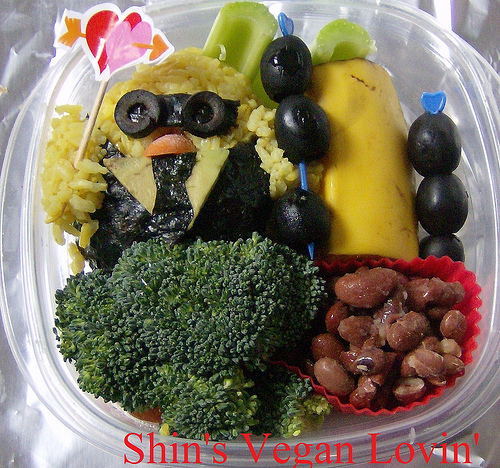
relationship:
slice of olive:
[110, 90, 164, 140] [107, 93, 161, 145]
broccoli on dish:
[43, 223, 355, 434] [1, 2, 483, 456]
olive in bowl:
[407, 107, 469, 179] [0, 0, 500, 468]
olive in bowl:
[410, 170, 476, 233] [0, 0, 500, 468]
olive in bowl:
[420, 231, 475, 266] [0, 0, 500, 468]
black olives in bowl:
[258, 33, 331, 246] [0, 0, 500, 468]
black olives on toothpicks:
[258, 33, 331, 246] [276, 4, 318, 258]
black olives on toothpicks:
[258, 33, 331, 246] [419, 85, 446, 114]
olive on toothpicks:
[405, 107, 462, 178] [419, 85, 446, 114]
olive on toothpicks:
[413, 169, 470, 235] [276, 4, 318, 258]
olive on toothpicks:
[420, 232, 466, 265] [419, 85, 446, 114]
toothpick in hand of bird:
[71, 69, 128, 161] [19, 45, 322, 267]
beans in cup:
[307, 265, 469, 409] [255, 255, 482, 415]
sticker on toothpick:
[51, 0, 176, 81] [73, 77, 108, 165]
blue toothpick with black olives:
[280, 10, 319, 257] [260, 32, 330, 243]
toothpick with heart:
[72, 79, 111, 172] [81, 3, 144, 83]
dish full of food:
[0, 0, 499, 468] [78, 40, 478, 427]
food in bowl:
[37, 0, 471, 445] [0, 0, 500, 468]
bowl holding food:
[0, 0, 500, 468] [37, 0, 471, 445]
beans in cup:
[307, 265, 469, 409] [284, 251, 484, 414]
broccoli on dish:
[43, 231, 329, 441] [0, 0, 499, 468]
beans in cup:
[307, 261, 471, 409] [284, 251, 484, 414]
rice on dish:
[38, 45, 324, 269] [0, 0, 499, 468]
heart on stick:
[81, 8, 143, 80] [71, 75, 106, 170]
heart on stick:
[103, 20, 154, 77] [71, 75, 106, 170]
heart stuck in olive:
[417, 86, 450, 113] [408, 111, 461, 178]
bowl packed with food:
[0, 0, 500, 468] [59, 51, 406, 368]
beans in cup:
[307, 265, 469, 409] [299, 242, 485, 423]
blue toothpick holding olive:
[277, 12, 315, 261] [259, 34, 313, 104]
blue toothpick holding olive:
[277, 12, 315, 261] [276, 95, 330, 164]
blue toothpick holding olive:
[277, 12, 315, 261] [275, 187, 327, 244]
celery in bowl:
[201, 2, 276, 90] [1, 4, 498, 465]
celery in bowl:
[311, 17, 372, 65] [1, 4, 498, 465]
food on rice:
[42, 10, 481, 395] [36, 48, 300, 218]